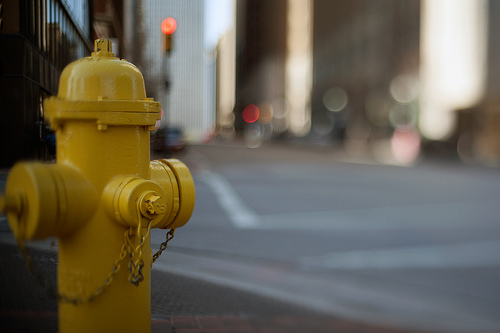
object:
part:
[407, 232, 448, 265]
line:
[301, 230, 484, 275]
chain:
[117, 193, 154, 289]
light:
[155, 14, 180, 34]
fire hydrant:
[0, 37, 197, 333]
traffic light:
[158, 14, 177, 60]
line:
[193, 153, 263, 230]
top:
[92, 36, 114, 54]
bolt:
[145, 193, 168, 217]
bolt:
[2, 190, 20, 220]